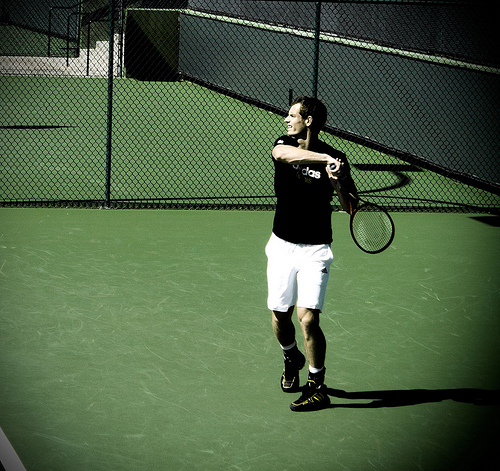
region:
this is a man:
[272, 96, 355, 346]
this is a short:
[269, 245, 331, 302]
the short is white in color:
[273, 255, 283, 282]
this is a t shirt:
[272, 170, 322, 231]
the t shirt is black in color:
[281, 204, 302, 220]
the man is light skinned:
[288, 149, 300, 160]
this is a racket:
[347, 192, 395, 259]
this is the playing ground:
[37, 229, 219, 424]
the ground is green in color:
[96, 335, 173, 434]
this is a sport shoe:
[295, 391, 332, 402]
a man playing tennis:
[231, 75, 407, 433]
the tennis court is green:
[84, 260, 164, 348]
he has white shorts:
[243, 210, 417, 418]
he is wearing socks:
[243, 322, 371, 454]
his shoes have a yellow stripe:
[222, 268, 387, 437]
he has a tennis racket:
[170, 48, 453, 459]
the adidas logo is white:
[212, 68, 412, 344]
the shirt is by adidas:
[231, 84, 421, 294]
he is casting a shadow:
[208, 77, 448, 449]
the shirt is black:
[228, 66, 435, 428]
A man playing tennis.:
[264, 93, 396, 413]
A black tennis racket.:
[330, 162, 396, 255]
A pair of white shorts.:
[264, 232, 334, 312]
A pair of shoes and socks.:
[278, 340, 333, 412]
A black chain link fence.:
[0, 0, 498, 214]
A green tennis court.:
[3, 74, 498, 468]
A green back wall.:
[0, 2, 499, 183]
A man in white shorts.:
[263, 95, 358, 413]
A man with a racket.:
[264, 93, 394, 412]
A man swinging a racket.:
[263, 92, 395, 411]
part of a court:
[356, 293, 420, 353]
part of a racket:
[358, 215, 383, 241]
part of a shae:
[381, 387, 451, 415]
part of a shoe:
[292, 400, 305, 410]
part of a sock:
[301, 357, 334, 382]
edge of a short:
[298, 299, 323, 319]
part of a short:
[256, 252, 306, 296]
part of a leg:
[277, 310, 300, 343]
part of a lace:
[281, 232, 306, 264]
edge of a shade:
[400, 396, 424, 411]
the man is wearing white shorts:
[260, 230, 332, 316]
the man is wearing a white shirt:
[265, 134, 356, 246]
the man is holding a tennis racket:
[325, 159, 393, 255]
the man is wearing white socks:
[272, 330, 327, 380]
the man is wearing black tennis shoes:
[275, 342, 332, 414]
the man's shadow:
[325, 377, 498, 413]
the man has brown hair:
[290, 92, 330, 139]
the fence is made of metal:
[2, 0, 494, 210]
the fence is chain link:
[5, 0, 496, 208]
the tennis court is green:
[0, 71, 497, 469]